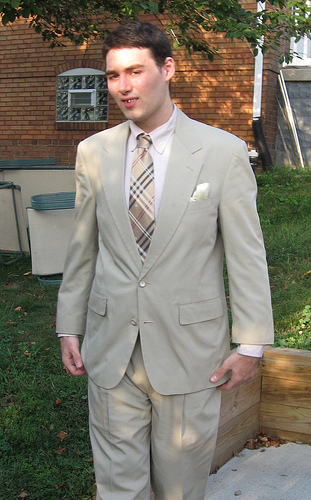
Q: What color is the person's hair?
A: Brown.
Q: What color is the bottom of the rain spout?
A: Black.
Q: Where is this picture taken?
A: In the backyard.